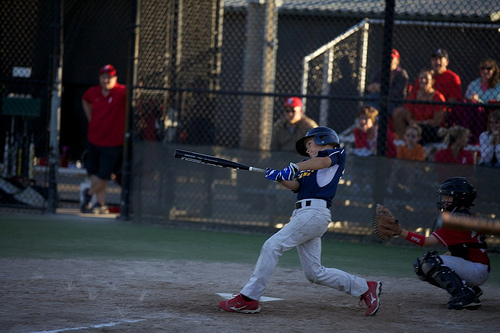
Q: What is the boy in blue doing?
A: Batting.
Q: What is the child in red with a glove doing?
A: Catching.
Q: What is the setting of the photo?
A: Little league baseball game.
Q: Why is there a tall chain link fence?
A: To protect the public from balls.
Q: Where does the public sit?
A: In the bleachers behind the fence.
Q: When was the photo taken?
A: In the afternoon.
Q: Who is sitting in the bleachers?
A: The fans and parents.